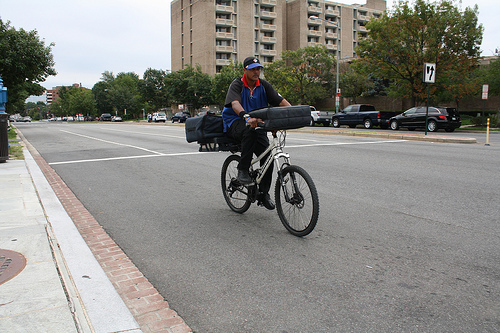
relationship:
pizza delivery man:
[238, 106, 316, 129] [211, 56, 299, 202]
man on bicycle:
[211, 56, 299, 202] [217, 159, 334, 238]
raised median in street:
[351, 123, 470, 157] [92, 125, 225, 226]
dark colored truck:
[395, 105, 457, 127] [333, 105, 425, 130]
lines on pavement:
[47, 127, 178, 165] [66, 137, 159, 178]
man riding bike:
[222, 56, 299, 185] [217, 159, 334, 238]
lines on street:
[50, 127, 178, 172] [92, 125, 225, 226]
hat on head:
[231, 55, 269, 72] [232, 53, 268, 88]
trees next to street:
[99, 88, 160, 106] [92, 125, 225, 226]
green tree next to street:
[100, 81, 162, 102] [92, 125, 225, 226]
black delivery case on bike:
[238, 106, 316, 129] [217, 159, 334, 238]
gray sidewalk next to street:
[3, 176, 43, 214] [92, 125, 225, 226]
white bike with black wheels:
[250, 130, 288, 192] [217, 159, 334, 238]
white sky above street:
[89, 10, 160, 50] [92, 125, 225, 226]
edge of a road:
[14, 139, 85, 222] [93, 136, 151, 180]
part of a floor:
[116, 152, 176, 178] [93, 136, 151, 180]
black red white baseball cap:
[231, 55, 269, 72] [243, 58, 269, 73]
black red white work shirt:
[216, 73, 282, 118] [224, 79, 307, 130]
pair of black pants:
[223, 105, 272, 188] [230, 122, 269, 167]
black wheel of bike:
[279, 167, 321, 235] [217, 159, 334, 238]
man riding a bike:
[211, 56, 299, 202] [217, 159, 334, 238]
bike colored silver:
[217, 159, 334, 238] [224, 150, 293, 188]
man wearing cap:
[211, 56, 299, 202] [243, 58, 269, 73]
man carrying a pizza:
[211, 56, 299, 202] [238, 106, 316, 129]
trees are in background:
[99, 88, 160, 106] [138, 72, 200, 109]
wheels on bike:
[217, 159, 334, 238] [220, 123, 322, 236]